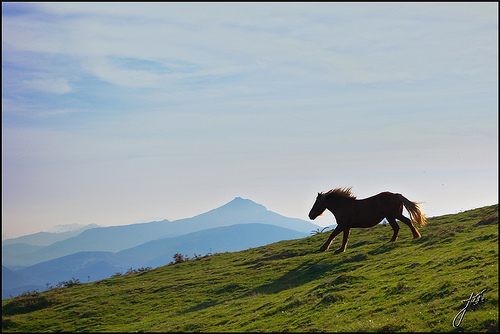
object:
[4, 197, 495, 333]
field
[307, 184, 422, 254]
horse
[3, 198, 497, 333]
hill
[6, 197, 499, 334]
grass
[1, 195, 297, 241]
mountains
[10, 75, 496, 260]
background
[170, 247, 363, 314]
shadow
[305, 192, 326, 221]
head